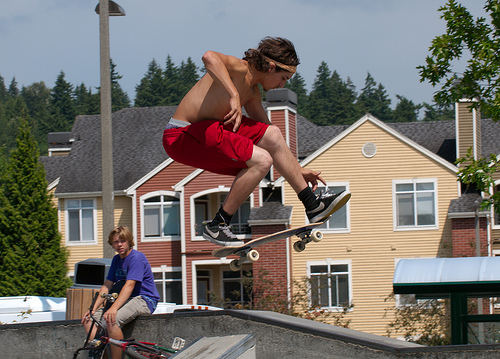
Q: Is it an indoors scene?
A: Yes, it is indoors.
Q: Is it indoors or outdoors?
A: It is indoors.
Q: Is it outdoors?
A: No, it is indoors.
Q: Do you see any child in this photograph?
A: Yes, there is a child.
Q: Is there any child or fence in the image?
A: Yes, there is a child.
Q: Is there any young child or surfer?
A: Yes, there is a young child.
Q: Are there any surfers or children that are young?
A: Yes, the child is young.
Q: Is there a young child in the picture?
A: Yes, there is a young child.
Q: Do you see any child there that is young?
A: Yes, there is a child that is young.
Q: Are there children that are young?
A: Yes, there is a child that is young.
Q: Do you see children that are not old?
A: Yes, there is an young child.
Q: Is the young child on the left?
A: Yes, the child is on the left of the image.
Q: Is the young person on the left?
A: Yes, the child is on the left of the image.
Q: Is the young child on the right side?
A: No, the child is on the left of the image.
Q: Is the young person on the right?
A: No, the child is on the left of the image.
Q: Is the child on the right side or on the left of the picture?
A: The child is on the left of the image.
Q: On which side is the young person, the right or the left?
A: The child is on the left of the image.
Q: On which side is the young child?
A: The child is on the left of the image.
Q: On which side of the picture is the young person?
A: The child is on the left of the image.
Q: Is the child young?
A: Yes, the child is young.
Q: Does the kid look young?
A: Yes, the kid is young.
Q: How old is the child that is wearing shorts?
A: The child is young.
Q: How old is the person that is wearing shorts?
A: The child is young.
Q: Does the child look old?
A: No, the child is young.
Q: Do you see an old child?
A: No, there is a child but he is young.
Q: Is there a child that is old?
A: No, there is a child but he is young.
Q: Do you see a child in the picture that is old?
A: No, there is a child but he is young.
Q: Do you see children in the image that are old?
A: No, there is a child but he is young.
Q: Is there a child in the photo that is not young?
A: No, there is a child but he is young.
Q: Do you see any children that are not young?
A: No, there is a child but he is young.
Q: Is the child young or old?
A: The child is young.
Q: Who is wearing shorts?
A: The child is wearing shorts.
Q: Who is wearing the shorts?
A: The child is wearing shorts.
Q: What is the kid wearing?
A: The kid is wearing shorts.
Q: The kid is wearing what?
A: The kid is wearing shorts.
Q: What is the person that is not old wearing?
A: The kid is wearing shorts.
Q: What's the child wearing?
A: The kid is wearing shorts.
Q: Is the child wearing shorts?
A: Yes, the child is wearing shorts.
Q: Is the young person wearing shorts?
A: Yes, the child is wearing shorts.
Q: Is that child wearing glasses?
A: No, the child is wearing shorts.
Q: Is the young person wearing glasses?
A: No, the child is wearing shorts.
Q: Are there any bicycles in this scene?
A: Yes, there is a bicycle.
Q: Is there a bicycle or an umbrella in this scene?
A: Yes, there is a bicycle.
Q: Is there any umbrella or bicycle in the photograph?
A: Yes, there is a bicycle.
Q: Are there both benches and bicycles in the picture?
A: No, there is a bicycle but no benches.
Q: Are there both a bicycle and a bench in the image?
A: No, there is a bicycle but no benches.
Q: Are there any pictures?
A: No, there are no pictures.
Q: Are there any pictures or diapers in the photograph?
A: No, there are no pictures or diapers.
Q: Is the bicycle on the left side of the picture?
A: Yes, the bicycle is on the left of the image.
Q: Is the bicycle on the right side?
A: No, the bicycle is on the left of the image.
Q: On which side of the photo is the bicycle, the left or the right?
A: The bicycle is on the left of the image.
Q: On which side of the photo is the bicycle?
A: The bicycle is on the left of the image.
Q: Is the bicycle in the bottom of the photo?
A: Yes, the bicycle is in the bottom of the image.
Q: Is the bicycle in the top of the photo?
A: No, the bicycle is in the bottom of the image.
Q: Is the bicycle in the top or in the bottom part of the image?
A: The bicycle is in the bottom of the image.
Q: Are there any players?
A: No, there are no players.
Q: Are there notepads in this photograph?
A: No, there are no notepads.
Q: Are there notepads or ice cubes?
A: No, there are no notepads or ice cubes.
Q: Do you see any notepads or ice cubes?
A: No, there are no notepads or ice cubes.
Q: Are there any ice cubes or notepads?
A: No, there are no notepads or ice cubes.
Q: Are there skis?
A: No, there are no skis.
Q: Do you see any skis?
A: No, there are no skis.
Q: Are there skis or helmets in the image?
A: No, there are no skis or helmets.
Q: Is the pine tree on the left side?
A: Yes, the pine tree is on the left of the image.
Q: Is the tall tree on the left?
A: Yes, the pine tree is on the left of the image.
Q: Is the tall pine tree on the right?
A: No, the pine tree is on the left of the image.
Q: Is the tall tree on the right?
A: No, the pine tree is on the left of the image.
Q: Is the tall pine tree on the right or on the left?
A: The pine tree is on the left of the image.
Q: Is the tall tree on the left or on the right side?
A: The pine tree is on the left of the image.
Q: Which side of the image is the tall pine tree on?
A: The pine tree is on the left of the image.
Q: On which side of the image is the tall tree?
A: The pine tree is on the left of the image.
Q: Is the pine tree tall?
A: Yes, the pine tree is tall.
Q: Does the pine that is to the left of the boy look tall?
A: Yes, the pine tree is tall.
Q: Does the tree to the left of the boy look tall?
A: Yes, the pine tree is tall.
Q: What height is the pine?
A: The pine is tall.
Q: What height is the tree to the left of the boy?
A: The pine is tall.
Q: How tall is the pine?
A: The pine is tall.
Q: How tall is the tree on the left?
A: The pine is tall.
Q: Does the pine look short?
A: No, the pine is tall.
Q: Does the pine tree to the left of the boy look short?
A: No, the pine tree is tall.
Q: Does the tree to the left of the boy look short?
A: No, the pine tree is tall.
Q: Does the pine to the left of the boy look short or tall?
A: The pine is tall.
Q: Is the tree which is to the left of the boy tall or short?
A: The pine is tall.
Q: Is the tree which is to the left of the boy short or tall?
A: The pine is tall.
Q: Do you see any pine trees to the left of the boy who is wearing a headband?
A: Yes, there is a pine tree to the left of the boy.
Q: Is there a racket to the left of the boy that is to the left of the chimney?
A: No, there is a pine tree to the left of the boy.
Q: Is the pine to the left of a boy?
A: Yes, the pine is to the left of a boy.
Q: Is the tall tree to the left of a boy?
A: Yes, the pine is to the left of a boy.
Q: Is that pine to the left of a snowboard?
A: No, the pine is to the left of a boy.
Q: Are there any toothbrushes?
A: No, there are no toothbrushes.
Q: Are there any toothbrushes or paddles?
A: No, there are no toothbrushes or paddles.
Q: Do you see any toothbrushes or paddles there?
A: No, there are no toothbrushes or paddles.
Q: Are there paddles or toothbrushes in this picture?
A: No, there are no toothbrushes or paddles.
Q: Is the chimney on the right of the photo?
A: Yes, the chimney is on the right of the image.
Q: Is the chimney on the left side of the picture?
A: No, the chimney is on the right of the image.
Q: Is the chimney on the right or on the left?
A: The chimney is on the right of the image.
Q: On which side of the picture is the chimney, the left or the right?
A: The chimney is on the right of the image.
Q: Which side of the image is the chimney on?
A: The chimney is on the right of the image.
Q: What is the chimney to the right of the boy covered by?
A: The chimney is covered by the tree.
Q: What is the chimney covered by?
A: The chimney is covered by the tree.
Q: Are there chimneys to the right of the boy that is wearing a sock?
A: Yes, there is a chimney to the right of the boy.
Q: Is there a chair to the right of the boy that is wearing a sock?
A: No, there is a chimney to the right of the boy.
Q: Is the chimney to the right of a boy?
A: Yes, the chimney is to the right of a boy.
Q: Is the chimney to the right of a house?
A: No, the chimney is to the right of a boy.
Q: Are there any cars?
A: No, there are no cars.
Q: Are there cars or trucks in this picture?
A: No, there are no cars or trucks.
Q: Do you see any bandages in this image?
A: No, there are no bandages.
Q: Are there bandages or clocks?
A: No, there are no bandages or clocks.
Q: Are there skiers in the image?
A: No, there are no skiers.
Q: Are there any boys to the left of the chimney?
A: Yes, there is a boy to the left of the chimney.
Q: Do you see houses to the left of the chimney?
A: No, there is a boy to the left of the chimney.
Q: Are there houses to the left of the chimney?
A: No, there is a boy to the left of the chimney.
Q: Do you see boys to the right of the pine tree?
A: Yes, there is a boy to the right of the pine tree.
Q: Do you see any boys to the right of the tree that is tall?
A: Yes, there is a boy to the right of the pine tree.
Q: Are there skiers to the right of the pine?
A: No, there is a boy to the right of the pine.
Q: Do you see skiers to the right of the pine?
A: No, there is a boy to the right of the pine.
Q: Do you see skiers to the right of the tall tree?
A: No, there is a boy to the right of the pine.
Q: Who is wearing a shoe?
A: The boy is wearing a shoe.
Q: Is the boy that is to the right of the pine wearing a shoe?
A: Yes, the boy is wearing a shoe.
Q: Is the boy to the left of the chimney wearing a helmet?
A: No, the boy is wearing a shoe.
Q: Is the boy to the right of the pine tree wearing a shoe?
A: Yes, the boy is wearing a shoe.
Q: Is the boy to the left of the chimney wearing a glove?
A: No, the boy is wearing a shoe.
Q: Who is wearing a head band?
A: The boy is wearing a head band.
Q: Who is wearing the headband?
A: The boy is wearing a head band.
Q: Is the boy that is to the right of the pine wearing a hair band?
A: Yes, the boy is wearing a hair band.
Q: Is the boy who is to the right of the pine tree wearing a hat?
A: No, the boy is wearing a hair band.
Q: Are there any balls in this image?
A: No, there are no balls.